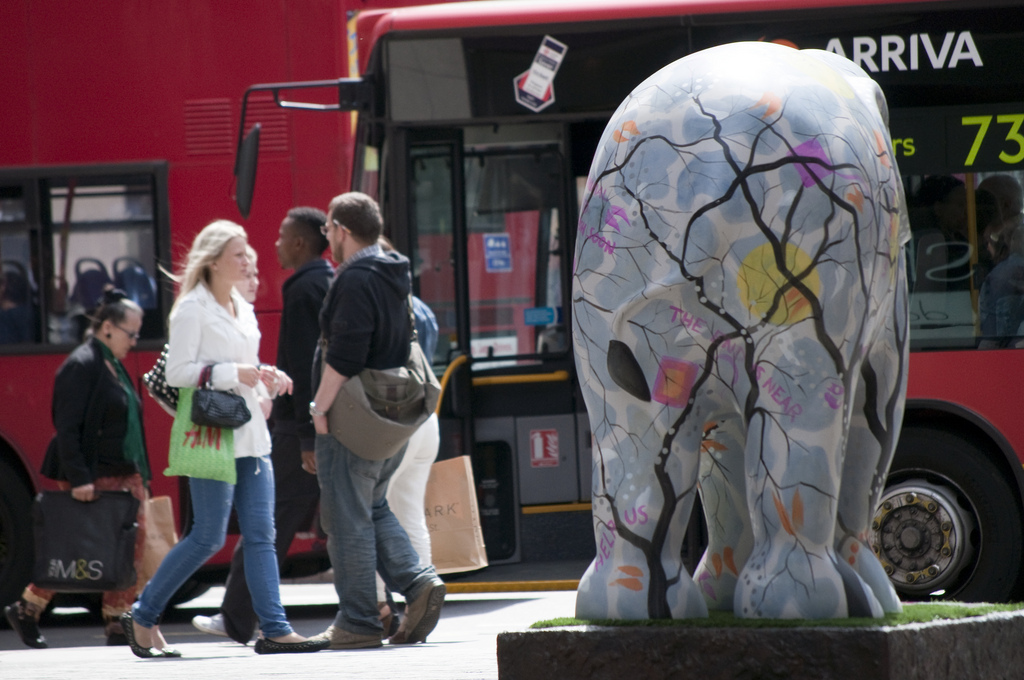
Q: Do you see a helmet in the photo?
A: No, there are no helmets.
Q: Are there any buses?
A: Yes, there is a bus.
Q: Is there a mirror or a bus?
A: Yes, there is a bus.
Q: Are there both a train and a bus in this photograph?
A: No, there is a bus but no trains.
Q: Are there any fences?
A: No, there are no fences.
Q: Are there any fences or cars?
A: No, there are no fences or cars.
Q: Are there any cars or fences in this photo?
A: No, there are no fences or cars.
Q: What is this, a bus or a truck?
A: This is a bus.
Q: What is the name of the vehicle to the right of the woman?
A: The vehicle is a bus.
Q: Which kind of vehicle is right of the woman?
A: The vehicle is a bus.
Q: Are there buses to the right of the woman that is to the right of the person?
A: Yes, there is a bus to the right of the woman.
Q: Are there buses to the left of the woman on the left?
A: No, the bus is to the right of the woman.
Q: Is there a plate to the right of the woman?
A: No, there is a bus to the right of the woman.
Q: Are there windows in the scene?
A: Yes, there is a window.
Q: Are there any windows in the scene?
A: Yes, there is a window.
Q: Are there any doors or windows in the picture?
A: Yes, there is a window.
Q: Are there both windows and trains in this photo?
A: No, there is a window but no trains.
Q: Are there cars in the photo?
A: No, there are no cars.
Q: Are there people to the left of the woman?
A: Yes, there is a person to the left of the woman.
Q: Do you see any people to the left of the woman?
A: Yes, there is a person to the left of the woman.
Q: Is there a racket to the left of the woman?
A: No, there is a person to the left of the woman.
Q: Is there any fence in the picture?
A: No, there are no fences.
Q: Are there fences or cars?
A: No, there are no fences or cars.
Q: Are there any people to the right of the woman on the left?
A: Yes, there is a person to the right of the woman.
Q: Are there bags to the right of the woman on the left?
A: No, there is a person to the right of the woman.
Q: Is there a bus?
A: Yes, there is a bus.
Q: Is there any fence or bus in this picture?
A: Yes, there is a bus.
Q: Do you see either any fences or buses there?
A: Yes, there is a bus.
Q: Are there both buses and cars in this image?
A: No, there is a bus but no cars.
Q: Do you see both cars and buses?
A: No, there is a bus but no cars.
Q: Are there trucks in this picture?
A: No, there are no trucks.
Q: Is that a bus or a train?
A: That is a bus.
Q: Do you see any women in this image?
A: Yes, there is a woman.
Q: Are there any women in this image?
A: Yes, there is a woman.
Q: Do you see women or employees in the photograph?
A: Yes, there is a woman.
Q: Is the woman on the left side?
A: Yes, the woman is on the left of the image.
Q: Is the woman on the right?
A: No, the woman is on the left of the image.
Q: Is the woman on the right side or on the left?
A: The woman is on the left of the image.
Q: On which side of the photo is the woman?
A: The woman is on the left of the image.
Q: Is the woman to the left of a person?
A: Yes, the woman is to the left of a person.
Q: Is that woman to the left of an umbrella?
A: No, the woman is to the left of a person.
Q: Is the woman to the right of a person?
A: No, the woman is to the left of a person.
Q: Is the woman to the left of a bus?
A: Yes, the woman is to the left of a bus.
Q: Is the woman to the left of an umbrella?
A: No, the woman is to the left of a bus.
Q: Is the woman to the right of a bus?
A: No, the woman is to the left of a bus.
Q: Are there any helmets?
A: No, there are no helmets.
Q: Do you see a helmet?
A: No, there are no helmets.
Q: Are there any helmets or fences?
A: No, there are no helmets or fences.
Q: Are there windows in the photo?
A: Yes, there is a window.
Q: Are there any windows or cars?
A: Yes, there is a window.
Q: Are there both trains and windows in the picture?
A: No, there is a window but no trains.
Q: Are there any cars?
A: No, there are no cars.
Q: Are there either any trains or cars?
A: No, there are no cars or trains.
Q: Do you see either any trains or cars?
A: No, there are no cars or trains.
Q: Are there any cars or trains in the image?
A: No, there are no cars or trains.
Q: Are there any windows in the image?
A: Yes, there is a window.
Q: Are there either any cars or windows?
A: Yes, there is a window.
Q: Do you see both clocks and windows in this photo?
A: No, there is a window but no clocks.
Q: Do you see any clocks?
A: No, there are no clocks.